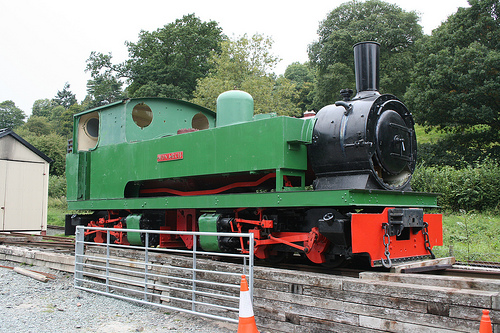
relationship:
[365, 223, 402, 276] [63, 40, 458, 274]
chain on engine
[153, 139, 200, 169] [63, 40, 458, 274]
label on engine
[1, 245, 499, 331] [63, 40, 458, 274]
plank by engine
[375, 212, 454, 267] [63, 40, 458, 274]
chains on engine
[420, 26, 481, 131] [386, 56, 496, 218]
tree on hill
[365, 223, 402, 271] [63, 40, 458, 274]
chain on engine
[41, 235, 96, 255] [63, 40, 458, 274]
track behind engine